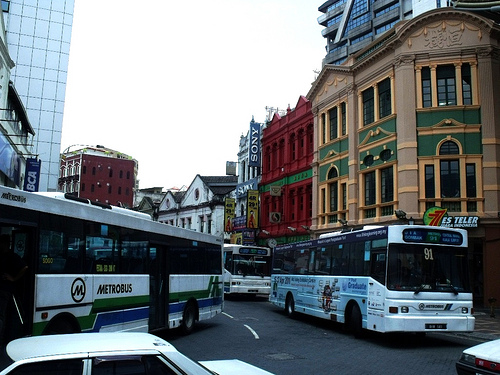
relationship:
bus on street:
[267, 223, 476, 336] [167, 299, 472, 374]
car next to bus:
[0, 330, 278, 374] [0, 183, 224, 340]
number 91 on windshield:
[423, 246, 436, 260] [385, 241, 472, 295]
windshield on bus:
[385, 241, 472, 295] [267, 223, 476, 336]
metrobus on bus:
[94, 282, 134, 295] [0, 183, 224, 340]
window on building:
[82, 164, 89, 175] [60, 143, 140, 206]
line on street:
[243, 322, 261, 341] [167, 299, 472, 374]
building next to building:
[259, 94, 313, 248] [306, 7, 498, 309]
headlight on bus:
[399, 304, 409, 315] [267, 223, 476, 336]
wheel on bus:
[285, 292, 297, 317] [267, 223, 476, 336]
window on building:
[415, 59, 478, 109] [306, 7, 498, 309]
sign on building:
[248, 121, 262, 166] [259, 94, 313, 248]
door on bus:
[148, 243, 169, 333] [0, 183, 224, 340]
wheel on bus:
[345, 302, 363, 338] [267, 223, 476, 336]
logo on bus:
[69, 276, 88, 303] [0, 183, 224, 340]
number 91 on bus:
[423, 246, 436, 260] [267, 223, 476, 336]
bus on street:
[0, 183, 224, 340] [167, 299, 472, 374]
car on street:
[0, 330, 278, 374] [167, 299, 472, 374]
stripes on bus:
[78, 288, 223, 331] [0, 183, 224, 340]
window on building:
[45, 20, 65, 43] [2, 0, 77, 192]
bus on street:
[223, 243, 271, 297] [167, 299, 472, 374]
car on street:
[454, 334, 498, 373] [167, 299, 472, 374]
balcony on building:
[313, 6, 348, 26] [314, 0, 409, 66]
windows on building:
[344, 14, 371, 31] [314, 0, 409, 66]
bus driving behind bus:
[223, 243, 271, 297] [267, 223, 476, 336]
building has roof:
[155, 172, 243, 234] [183, 172, 242, 206]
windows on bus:
[270, 239, 388, 277] [267, 223, 476, 336]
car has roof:
[0, 330, 278, 374] [7, 331, 164, 358]